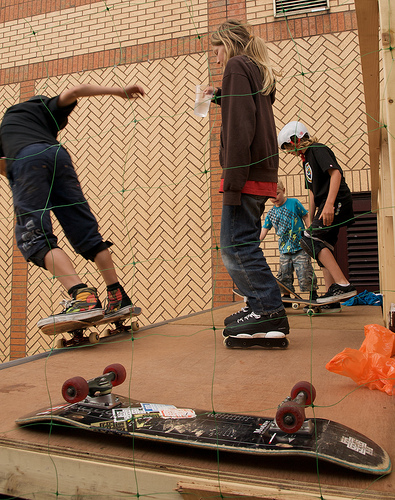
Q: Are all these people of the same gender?
A: No, they are both male and female.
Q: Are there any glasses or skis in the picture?
A: No, there are no glasses or skis.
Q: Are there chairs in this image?
A: No, there are no chairs.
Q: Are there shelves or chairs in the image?
A: No, there are no chairs or shelves.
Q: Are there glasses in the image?
A: No, there are no glasses.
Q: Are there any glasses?
A: No, there are no glasses.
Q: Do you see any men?
A: No, there are no men.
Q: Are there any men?
A: No, there are no men.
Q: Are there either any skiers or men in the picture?
A: No, there are no men or skiers.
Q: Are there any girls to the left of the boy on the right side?
A: Yes, there is a girl to the left of the boy.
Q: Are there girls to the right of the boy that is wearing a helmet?
A: No, the girl is to the left of the boy.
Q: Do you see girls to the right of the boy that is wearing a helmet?
A: No, the girl is to the left of the boy.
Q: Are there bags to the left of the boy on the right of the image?
A: No, there is a girl to the left of the boy.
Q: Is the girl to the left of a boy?
A: Yes, the girl is to the left of a boy.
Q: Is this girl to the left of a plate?
A: No, the girl is to the left of a boy.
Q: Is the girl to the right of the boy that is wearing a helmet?
A: No, the girl is to the left of the boy.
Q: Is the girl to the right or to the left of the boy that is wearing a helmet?
A: The girl is to the left of the boy.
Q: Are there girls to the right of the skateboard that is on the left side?
A: Yes, there is a girl to the right of the skateboard.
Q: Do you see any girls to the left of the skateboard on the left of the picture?
A: No, the girl is to the right of the skateboard.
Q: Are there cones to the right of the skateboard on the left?
A: No, there is a girl to the right of the skateboard.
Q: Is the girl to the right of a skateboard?
A: Yes, the girl is to the right of a skateboard.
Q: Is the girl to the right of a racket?
A: No, the girl is to the right of a skateboard.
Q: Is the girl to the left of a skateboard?
A: No, the girl is to the right of a skateboard.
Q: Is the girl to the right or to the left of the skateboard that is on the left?
A: The girl is to the right of the skateboard.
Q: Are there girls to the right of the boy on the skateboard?
A: Yes, there is a girl to the right of the boy.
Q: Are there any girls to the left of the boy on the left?
A: No, the girl is to the right of the boy.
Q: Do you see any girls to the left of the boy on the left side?
A: No, the girl is to the right of the boy.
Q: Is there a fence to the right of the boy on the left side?
A: No, there is a girl to the right of the boy.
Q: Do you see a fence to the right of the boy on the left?
A: No, there is a girl to the right of the boy.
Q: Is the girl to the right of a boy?
A: Yes, the girl is to the right of a boy.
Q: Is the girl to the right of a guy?
A: No, the girl is to the right of a boy.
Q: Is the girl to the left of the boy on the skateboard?
A: No, the girl is to the right of the boy.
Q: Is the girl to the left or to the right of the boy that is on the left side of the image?
A: The girl is to the right of the boy.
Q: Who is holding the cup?
A: The girl is holding the cup.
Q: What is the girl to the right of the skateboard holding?
A: The girl is holding the cup.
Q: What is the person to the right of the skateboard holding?
A: The girl is holding the cup.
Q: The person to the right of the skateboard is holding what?
A: The girl is holding the cup.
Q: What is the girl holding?
A: The girl is holding the cup.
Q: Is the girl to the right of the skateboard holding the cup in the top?
A: Yes, the girl is holding the cup.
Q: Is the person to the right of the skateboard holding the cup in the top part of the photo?
A: Yes, the girl is holding the cup.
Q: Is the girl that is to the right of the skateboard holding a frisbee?
A: No, the girl is holding the cup.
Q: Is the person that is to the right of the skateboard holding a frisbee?
A: No, the girl is holding the cup.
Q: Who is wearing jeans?
A: The girl is wearing jeans.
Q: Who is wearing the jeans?
A: The girl is wearing jeans.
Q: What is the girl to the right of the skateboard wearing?
A: The girl is wearing jeans.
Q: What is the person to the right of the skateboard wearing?
A: The girl is wearing jeans.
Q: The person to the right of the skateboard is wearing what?
A: The girl is wearing jeans.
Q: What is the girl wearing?
A: The girl is wearing jeans.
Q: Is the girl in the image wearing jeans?
A: Yes, the girl is wearing jeans.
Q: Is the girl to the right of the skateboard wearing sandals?
A: No, the girl is wearing jeans.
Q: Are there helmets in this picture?
A: Yes, there is a helmet.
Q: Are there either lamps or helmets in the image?
A: Yes, there is a helmet.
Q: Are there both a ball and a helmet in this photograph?
A: No, there is a helmet but no balls.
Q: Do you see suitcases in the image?
A: No, there are no suitcases.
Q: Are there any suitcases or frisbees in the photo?
A: No, there are no suitcases or frisbees.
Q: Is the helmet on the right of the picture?
A: Yes, the helmet is on the right of the image.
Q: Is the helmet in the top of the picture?
A: Yes, the helmet is in the top of the image.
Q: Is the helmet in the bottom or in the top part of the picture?
A: The helmet is in the top of the image.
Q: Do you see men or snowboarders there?
A: No, there are no men or snowboarders.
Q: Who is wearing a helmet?
A: The boy is wearing a helmet.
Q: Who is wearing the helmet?
A: The boy is wearing a helmet.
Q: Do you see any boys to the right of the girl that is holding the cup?
A: Yes, there is a boy to the right of the girl.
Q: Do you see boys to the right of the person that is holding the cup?
A: Yes, there is a boy to the right of the girl.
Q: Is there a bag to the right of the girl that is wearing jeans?
A: No, there is a boy to the right of the girl.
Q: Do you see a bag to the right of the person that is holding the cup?
A: No, there is a boy to the right of the girl.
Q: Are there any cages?
A: No, there are no cages.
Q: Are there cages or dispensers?
A: No, there are no cages or dispensers.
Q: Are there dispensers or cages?
A: No, there are no cages or dispensers.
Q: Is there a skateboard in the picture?
A: Yes, there is a skateboard.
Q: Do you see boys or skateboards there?
A: Yes, there is a skateboard.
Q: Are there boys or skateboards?
A: Yes, there is a skateboard.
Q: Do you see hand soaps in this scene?
A: No, there are no hand soaps.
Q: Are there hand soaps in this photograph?
A: No, there are no hand soaps.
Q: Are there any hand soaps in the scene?
A: No, there are no hand soaps.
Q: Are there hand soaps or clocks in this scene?
A: No, there are no hand soaps or clocks.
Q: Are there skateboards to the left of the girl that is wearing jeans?
A: Yes, there is a skateboard to the left of the girl.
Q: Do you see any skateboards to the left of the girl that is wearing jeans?
A: Yes, there is a skateboard to the left of the girl.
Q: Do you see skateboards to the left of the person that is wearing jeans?
A: Yes, there is a skateboard to the left of the girl.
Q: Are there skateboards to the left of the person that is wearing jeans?
A: Yes, there is a skateboard to the left of the girl.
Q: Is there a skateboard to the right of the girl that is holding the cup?
A: No, the skateboard is to the left of the girl.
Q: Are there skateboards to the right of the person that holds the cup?
A: No, the skateboard is to the left of the girl.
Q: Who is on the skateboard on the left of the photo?
A: The boy is on the skateboard.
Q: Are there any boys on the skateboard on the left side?
A: Yes, there is a boy on the skateboard.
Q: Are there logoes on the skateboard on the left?
A: No, there is a boy on the skateboard.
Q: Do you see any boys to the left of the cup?
A: Yes, there is a boy to the left of the cup.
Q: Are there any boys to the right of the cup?
A: No, the boy is to the left of the cup.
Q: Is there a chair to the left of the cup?
A: No, there is a boy to the left of the cup.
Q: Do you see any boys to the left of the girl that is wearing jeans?
A: Yes, there is a boy to the left of the girl.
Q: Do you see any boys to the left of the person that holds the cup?
A: Yes, there is a boy to the left of the girl.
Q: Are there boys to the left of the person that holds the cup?
A: Yes, there is a boy to the left of the girl.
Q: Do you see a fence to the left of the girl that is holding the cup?
A: No, there is a boy to the left of the girl.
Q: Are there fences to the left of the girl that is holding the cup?
A: No, there is a boy to the left of the girl.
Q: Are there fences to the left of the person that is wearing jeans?
A: No, there is a boy to the left of the girl.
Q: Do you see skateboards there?
A: Yes, there is a skateboard.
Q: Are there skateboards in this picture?
A: Yes, there is a skateboard.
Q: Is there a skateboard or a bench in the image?
A: Yes, there is a skateboard.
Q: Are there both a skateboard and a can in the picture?
A: No, there is a skateboard but no cans.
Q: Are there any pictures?
A: No, there are no pictures.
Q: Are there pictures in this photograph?
A: No, there are no pictures.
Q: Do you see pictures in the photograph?
A: No, there are no pictures.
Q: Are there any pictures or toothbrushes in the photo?
A: No, there are no pictures or toothbrushes.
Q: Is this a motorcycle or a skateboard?
A: This is a skateboard.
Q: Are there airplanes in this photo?
A: No, there are no airplanes.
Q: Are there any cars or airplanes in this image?
A: No, there are no airplanes or cars.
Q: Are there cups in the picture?
A: Yes, there is a cup.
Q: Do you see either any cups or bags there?
A: Yes, there is a cup.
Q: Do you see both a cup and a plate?
A: No, there is a cup but no plates.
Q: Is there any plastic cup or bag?
A: Yes, there is a plastic cup.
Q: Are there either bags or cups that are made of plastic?
A: Yes, the cup is made of plastic.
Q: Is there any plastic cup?
A: Yes, there is a cup that is made of plastic.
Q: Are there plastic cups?
A: Yes, there is a cup that is made of plastic.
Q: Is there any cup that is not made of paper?
A: Yes, there is a cup that is made of plastic.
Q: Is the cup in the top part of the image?
A: Yes, the cup is in the top of the image.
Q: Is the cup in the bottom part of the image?
A: No, the cup is in the top of the image.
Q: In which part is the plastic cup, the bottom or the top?
A: The cup is in the top of the image.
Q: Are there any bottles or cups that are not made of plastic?
A: No, there is a cup but it is made of plastic.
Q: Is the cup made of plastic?
A: Yes, the cup is made of plastic.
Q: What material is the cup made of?
A: The cup is made of plastic.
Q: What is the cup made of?
A: The cup is made of plastic.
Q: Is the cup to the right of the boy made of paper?
A: No, the cup is made of plastic.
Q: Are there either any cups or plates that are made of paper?
A: No, there is a cup but it is made of plastic.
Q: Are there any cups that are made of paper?
A: No, there is a cup but it is made of plastic.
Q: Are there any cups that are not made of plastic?
A: No, there is a cup but it is made of plastic.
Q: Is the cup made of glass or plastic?
A: The cup is made of plastic.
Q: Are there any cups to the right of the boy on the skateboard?
A: Yes, there is a cup to the right of the boy.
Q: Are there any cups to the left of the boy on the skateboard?
A: No, the cup is to the right of the boy.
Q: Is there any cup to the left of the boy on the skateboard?
A: No, the cup is to the right of the boy.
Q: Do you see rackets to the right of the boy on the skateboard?
A: No, there is a cup to the right of the boy.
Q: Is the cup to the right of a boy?
A: Yes, the cup is to the right of a boy.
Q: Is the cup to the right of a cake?
A: No, the cup is to the right of a boy.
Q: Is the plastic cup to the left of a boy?
A: No, the cup is to the right of a boy.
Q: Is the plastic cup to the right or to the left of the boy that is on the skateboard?
A: The cup is to the right of the boy.